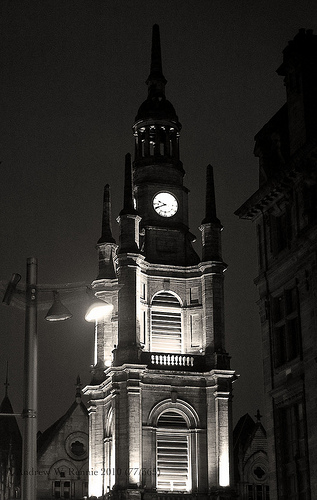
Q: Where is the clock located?
A: Near the top of the building.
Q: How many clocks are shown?
A: One.